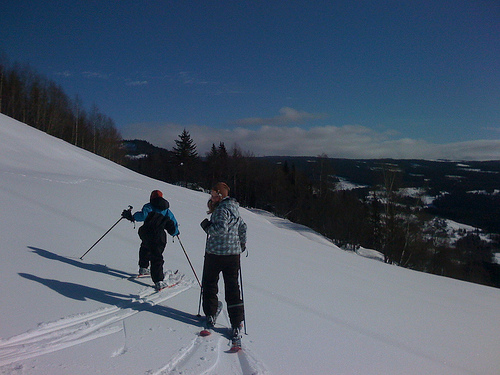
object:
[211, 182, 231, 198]
hat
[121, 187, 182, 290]
boy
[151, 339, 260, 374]
prints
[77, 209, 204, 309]
ski trail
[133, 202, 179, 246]
jacket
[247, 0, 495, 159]
skies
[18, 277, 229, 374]
ski prints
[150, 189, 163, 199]
hat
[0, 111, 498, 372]
mountain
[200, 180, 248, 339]
girl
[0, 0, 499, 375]
ground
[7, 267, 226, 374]
ski trail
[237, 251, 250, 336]
pole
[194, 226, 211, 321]
pole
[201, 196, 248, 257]
jacket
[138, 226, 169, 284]
pants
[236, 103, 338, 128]
cloud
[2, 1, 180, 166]
sky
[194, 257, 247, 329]
pants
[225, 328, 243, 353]
skis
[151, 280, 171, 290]
skis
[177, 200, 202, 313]
side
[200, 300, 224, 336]
skis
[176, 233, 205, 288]
ski pole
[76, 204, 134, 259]
ski pole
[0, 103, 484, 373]
snow